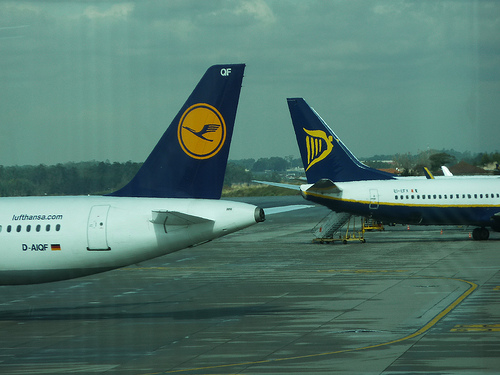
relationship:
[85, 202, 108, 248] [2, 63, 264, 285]
door of plane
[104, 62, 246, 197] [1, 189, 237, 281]
blue tail of airplane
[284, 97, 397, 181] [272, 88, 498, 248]
blue tail of airplane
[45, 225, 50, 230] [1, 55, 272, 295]
window on airplane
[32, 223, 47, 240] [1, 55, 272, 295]
window on airplane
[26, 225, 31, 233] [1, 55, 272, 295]
window on airplane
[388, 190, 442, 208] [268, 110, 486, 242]
window on airplane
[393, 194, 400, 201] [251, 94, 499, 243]
window on airplane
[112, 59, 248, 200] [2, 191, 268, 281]
blue tail of plane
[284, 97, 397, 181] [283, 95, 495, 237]
blue tail of plane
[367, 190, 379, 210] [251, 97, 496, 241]
door of plane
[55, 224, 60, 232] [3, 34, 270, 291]
window of plane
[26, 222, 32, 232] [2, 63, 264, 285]
window of plane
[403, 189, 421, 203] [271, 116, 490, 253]
window of plane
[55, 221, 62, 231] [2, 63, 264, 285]
window of plane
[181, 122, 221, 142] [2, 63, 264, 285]
logo on plane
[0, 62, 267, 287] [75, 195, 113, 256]
airplane has door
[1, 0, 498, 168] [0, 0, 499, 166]
clouds in sky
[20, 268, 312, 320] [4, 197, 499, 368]
shadow on runway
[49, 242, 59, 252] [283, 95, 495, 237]
flag on plane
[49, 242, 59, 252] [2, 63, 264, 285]
flag on plane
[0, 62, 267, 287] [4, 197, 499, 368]
airplane on runway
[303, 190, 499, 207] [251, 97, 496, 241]
stripe on plane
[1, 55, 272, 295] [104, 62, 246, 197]
airplane has blue tail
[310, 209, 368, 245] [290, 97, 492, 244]
stair case leading to airplane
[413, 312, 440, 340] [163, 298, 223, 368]
lines on ground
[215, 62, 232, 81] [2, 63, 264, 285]
letters on plane